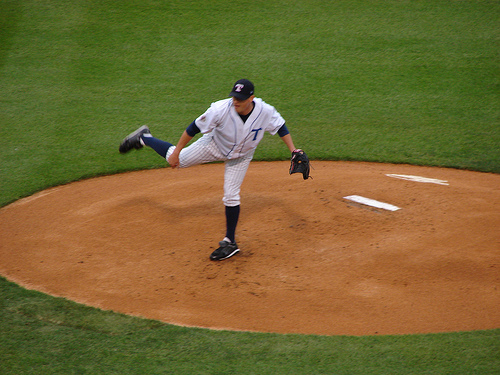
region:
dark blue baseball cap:
[225, 75, 259, 103]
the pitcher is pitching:
[98, 58, 325, 296]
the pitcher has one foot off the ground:
[79, 82, 217, 209]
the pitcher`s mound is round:
[5, 92, 499, 324]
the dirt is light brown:
[117, 146, 434, 314]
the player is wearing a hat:
[188, 55, 262, 117]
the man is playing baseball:
[97, 32, 337, 288]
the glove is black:
[256, 130, 336, 208]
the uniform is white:
[112, 57, 280, 235]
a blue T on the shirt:
[234, 110, 276, 170]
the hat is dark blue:
[221, 72, 256, 101]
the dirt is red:
[2, 142, 499, 346]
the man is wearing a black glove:
[284, 147, 319, 180]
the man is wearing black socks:
[141, 130, 241, 248]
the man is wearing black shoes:
[110, 115, 242, 265]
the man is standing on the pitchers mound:
[108, 72, 313, 265]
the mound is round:
[0, 143, 499, 351]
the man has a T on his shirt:
[248, 124, 264, 145]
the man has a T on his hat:
[233, 81, 247, 95]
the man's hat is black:
[226, 75, 258, 105]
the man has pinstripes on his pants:
[165, 131, 257, 216]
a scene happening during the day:
[2, 5, 497, 367]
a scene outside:
[5, 10, 490, 355]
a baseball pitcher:
[115, 63, 335, 294]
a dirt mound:
[13, 126, 498, 373]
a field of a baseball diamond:
[17, 19, 494, 367]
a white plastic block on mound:
[327, 180, 398, 237]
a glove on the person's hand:
[282, 145, 329, 194]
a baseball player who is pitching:
[107, 62, 333, 257]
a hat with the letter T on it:
[218, 69, 253, 112]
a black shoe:
[186, 219, 265, 286]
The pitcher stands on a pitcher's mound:
[117, 72, 317, 284]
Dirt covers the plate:
[334, 184, 399, 224]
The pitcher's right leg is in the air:
[114, 126, 221, 171]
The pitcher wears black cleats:
[214, 240, 241, 262]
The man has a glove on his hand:
[287, 143, 317, 185]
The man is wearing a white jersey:
[188, 103, 266, 163]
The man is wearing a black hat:
[229, 78, 258, 98]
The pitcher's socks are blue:
[140, 134, 175, 162]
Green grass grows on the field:
[12, 1, 464, 88]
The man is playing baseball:
[14, 10, 493, 370]